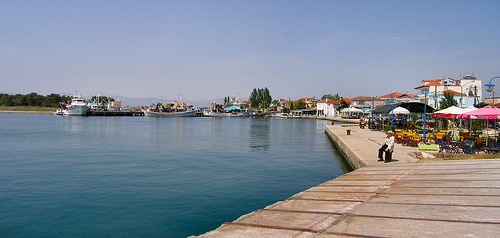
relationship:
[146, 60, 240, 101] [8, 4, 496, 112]
clouds are in sky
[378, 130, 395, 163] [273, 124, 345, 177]
person sitting by water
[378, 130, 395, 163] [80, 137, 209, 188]
person starring at water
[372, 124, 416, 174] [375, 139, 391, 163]
person wearing pants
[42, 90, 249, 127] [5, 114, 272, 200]
boats are on water